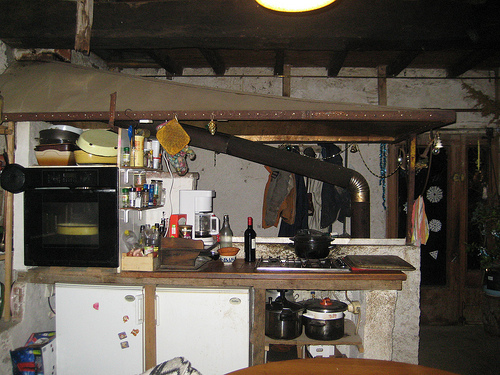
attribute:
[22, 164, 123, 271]
oven — black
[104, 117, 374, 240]
pipe — long, dark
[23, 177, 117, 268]
microwave — black, shiny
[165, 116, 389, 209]
pipe — long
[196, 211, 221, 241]
pot — coffee pot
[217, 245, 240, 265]
bowl — small, white, blue 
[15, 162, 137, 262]
oven — microwave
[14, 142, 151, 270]
oven — black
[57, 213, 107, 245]
pan — yellow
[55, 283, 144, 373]
fridge — small, white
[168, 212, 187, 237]
box — orange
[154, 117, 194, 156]
oven mitt — yellow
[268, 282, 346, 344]
pots — large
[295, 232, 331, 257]
pot — black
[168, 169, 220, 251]
coffee maker — white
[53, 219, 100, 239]
pan — yellow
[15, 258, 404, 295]
counter — wood